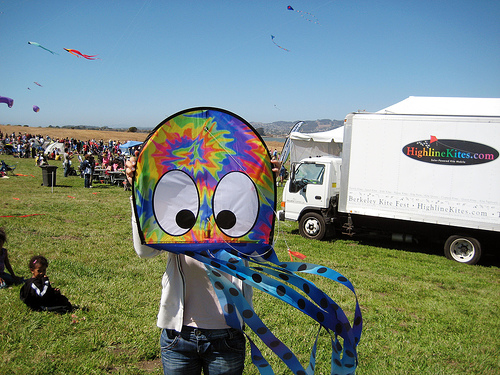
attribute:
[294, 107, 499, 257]
truck — white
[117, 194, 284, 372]
person — holding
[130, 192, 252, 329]
shirt — white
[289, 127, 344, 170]
shelter tent — spectator, white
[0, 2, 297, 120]
kites — flying, many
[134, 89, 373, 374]
kite — colorful, funny, large, polka dotted, black, blue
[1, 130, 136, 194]
crowd — watching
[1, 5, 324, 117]
kites — flying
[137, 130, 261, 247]
kite — multi-colored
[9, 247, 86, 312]
girl — sitting, little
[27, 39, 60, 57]
kite — aloft, flying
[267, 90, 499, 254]
truck — white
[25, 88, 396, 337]
kite — purple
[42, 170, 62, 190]
can — garbage, black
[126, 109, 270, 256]
kite — rainbow colored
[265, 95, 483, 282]
truck — white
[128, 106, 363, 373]
kite — Multi-colored, rainbow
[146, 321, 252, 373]
jeans — blue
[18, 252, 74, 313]
girl — little 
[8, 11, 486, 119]
sky — blue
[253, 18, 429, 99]
mountain — blue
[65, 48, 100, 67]
kite — red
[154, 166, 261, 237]
eyes — big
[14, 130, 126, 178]
group — large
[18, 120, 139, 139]
field — brown